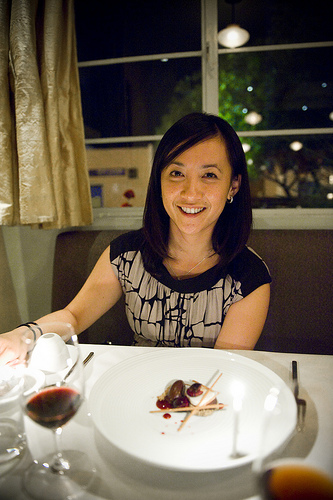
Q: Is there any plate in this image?
A: Yes, there is a plate.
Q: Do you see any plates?
A: Yes, there is a plate.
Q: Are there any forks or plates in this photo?
A: Yes, there is a plate.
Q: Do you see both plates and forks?
A: Yes, there are both a plate and a fork.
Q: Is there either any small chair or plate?
A: Yes, there is a small plate.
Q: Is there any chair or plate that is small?
A: Yes, the plate is small.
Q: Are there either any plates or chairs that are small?
A: Yes, the plate is small.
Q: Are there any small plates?
A: Yes, there is a small plate.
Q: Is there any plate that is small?
A: Yes, there is a plate that is small.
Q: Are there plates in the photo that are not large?
A: Yes, there is a small plate.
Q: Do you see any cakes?
A: No, there are no cakes.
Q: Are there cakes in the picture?
A: No, there are no cakes.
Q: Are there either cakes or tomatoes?
A: No, there are no cakes or tomatoes.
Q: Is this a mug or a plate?
A: This is a plate.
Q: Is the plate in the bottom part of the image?
A: Yes, the plate is in the bottom of the image.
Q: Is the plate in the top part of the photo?
A: No, the plate is in the bottom of the image.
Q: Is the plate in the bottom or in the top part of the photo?
A: The plate is in the bottom of the image.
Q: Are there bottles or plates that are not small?
A: No, there is a plate but it is small.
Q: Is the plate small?
A: Yes, the plate is small.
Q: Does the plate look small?
A: Yes, the plate is small.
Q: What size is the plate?
A: The plate is small.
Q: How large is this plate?
A: The plate is small.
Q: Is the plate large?
A: No, the plate is small.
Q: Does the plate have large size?
A: No, the plate is small.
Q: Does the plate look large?
A: No, the plate is small.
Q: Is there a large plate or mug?
A: No, there is a plate but it is small.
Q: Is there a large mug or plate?
A: No, there is a plate but it is small.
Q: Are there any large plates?
A: No, there is a plate but it is small.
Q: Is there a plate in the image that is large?
A: No, there is a plate but it is small.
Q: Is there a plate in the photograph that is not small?
A: No, there is a plate but it is small.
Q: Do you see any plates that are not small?
A: No, there is a plate but it is small.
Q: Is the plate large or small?
A: The plate is small.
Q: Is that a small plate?
A: Yes, that is a small plate.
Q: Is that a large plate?
A: No, that is a small plate.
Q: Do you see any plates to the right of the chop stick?
A: Yes, there is a plate to the right of the chop stick.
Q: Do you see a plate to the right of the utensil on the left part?
A: Yes, there is a plate to the right of the chop stick.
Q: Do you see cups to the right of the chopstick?
A: No, there is a plate to the right of the chopstick.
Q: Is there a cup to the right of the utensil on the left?
A: No, there is a plate to the right of the chopstick.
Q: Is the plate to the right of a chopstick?
A: Yes, the plate is to the right of a chopstick.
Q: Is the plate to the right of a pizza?
A: No, the plate is to the right of a chopstick.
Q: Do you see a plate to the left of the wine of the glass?
A: No, the plate is to the right of the wine.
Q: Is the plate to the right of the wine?
A: Yes, the plate is to the right of the wine.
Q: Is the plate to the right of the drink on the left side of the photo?
A: Yes, the plate is to the right of the wine.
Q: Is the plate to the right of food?
A: No, the plate is to the right of the wine.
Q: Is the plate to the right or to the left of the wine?
A: The plate is to the right of the wine.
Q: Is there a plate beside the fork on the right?
A: Yes, there is a plate beside the fork.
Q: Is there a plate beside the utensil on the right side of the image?
A: Yes, there is a plate beside the fork.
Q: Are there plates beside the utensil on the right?
A: Yes, there is a plate beside the fork.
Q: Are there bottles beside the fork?
A: No, there is a plate beside the fork.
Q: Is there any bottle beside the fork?
A: No, there is a plate beside the fork.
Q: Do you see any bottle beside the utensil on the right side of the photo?
A: No, there is a plate beside the fork.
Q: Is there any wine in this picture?
A: Yes, there is wine.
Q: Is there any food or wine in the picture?
A: Yes, there is wine.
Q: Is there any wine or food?
A: Yes, there is wine.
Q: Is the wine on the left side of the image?
A: Yes, the wine is on the left of the image.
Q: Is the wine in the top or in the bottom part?
A: The wine is in the bottom of the image.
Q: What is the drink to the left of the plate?
A: The drink is wine.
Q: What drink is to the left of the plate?
A: The drink is wine.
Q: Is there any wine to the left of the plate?
A: Yes, there is wine to the left of the plate.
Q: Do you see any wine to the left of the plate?
A: Yes, there is wine to the left of the plate.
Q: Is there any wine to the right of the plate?
A: No, the wine is to the left of the plate.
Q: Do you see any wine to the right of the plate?
A: No, the wine is to the left of the plate.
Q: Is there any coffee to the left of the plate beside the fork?
A: No, there is wine to the left of the plate.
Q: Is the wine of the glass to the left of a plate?
A: Yes, the wine is to the left of a plate.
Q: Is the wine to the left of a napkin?
A: No, the wine is to the left of a plate.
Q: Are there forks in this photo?
A: Yes, there is a fork.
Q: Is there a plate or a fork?
A: Yes, there is a fork.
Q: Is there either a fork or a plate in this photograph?
A: Yes, there is a fork.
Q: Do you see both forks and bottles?
A: No, there is a fork but no bottles.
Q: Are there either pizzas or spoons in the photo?
A: No, there are no spoons or pizzas.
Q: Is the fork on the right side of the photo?
A: Yes, the fork is on the right of the image.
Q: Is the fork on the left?
A: No, the fork is on the right of the image.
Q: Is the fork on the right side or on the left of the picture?
A: The fork is on the right of the image.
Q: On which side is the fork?
A: The fork is on the right of the image.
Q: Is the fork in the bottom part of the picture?
A: Yes, the fork is in the bottom of the image.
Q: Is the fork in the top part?
A: No, the fork is in the bottom of the image.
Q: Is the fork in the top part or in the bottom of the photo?
A: The fork is in the bottom of the image.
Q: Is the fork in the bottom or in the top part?
A: The fork is in the bottom of the image.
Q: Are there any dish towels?
A: No, there are no dish towels.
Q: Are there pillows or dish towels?
A: No, there are no dish towels or pillows.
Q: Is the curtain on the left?
A: Yes, the curtain is on the left of the image.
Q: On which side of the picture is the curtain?
A: The curtain is on the left of the image.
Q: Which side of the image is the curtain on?
A: The curtain is on the left of the image.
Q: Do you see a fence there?
A: No, there are no fences.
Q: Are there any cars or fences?
A: No, there are no fences or cars.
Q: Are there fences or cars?
A: No, there are no fences or cars.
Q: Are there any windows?
A: Yes, there is a window.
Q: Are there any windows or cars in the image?
A: Yes, there is a window.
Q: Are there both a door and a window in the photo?
A: No, there is a window but no doors.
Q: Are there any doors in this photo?
A: No, there are no doors.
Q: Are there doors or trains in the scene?
A: No, there are no doors or trains.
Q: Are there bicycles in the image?
A: No, there are no bicycles.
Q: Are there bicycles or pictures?
A: No, there are no bicycles or pictures.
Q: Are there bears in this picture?
A: No, there are no bears.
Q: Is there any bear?
A: No, there are no bears.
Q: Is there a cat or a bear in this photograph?
A: No, there are no bears or cats.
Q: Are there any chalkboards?
A: No, there are no chalkboards.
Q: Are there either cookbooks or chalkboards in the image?
A: No, there are no chalkboards or cookbooks.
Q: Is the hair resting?
A: Yes, the hair is resting.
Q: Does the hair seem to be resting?
A: Yes, the hair is resting.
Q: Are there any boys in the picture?
A: No, there are no boys.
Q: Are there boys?
A: No, there are no boys.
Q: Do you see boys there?
A: No, there are no boys.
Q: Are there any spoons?
A: No, there are no spoons.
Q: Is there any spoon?
A: No, there are no spoons.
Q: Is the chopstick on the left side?
A: Yes, the chopstick is on the left of the image.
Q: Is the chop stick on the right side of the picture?
A: No, the chop stick is on the left of the image.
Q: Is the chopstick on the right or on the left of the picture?
A: The chopstick is on the left of the image.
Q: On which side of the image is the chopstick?
A: The chopstick is on the left of the image.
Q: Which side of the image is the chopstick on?
A: The chopstick is on the left of the image.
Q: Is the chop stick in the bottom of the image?
A: Yes, the chop stick is in the bottom of the image.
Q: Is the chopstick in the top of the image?
A: No, the chopstick is in the bottom of the image.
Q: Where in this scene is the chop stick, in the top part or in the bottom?
A: The chop stick is in the bottom of the image.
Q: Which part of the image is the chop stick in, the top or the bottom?
A: The chop stick is in the bottom of the image.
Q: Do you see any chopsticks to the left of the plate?
A: Yes, there is a chopstick to the left of the plate.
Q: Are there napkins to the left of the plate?
A: No, there is a chopstick to the left of the plate.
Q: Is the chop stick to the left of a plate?
A: Yes, the chop stick is to the left of a plate.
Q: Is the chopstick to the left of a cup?
A: No, the chopstick is to the left of a plate.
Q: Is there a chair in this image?
A: No, there are no chairs.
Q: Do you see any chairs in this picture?
A: No, there are no chairs.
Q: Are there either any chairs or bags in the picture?
A: No, there are no chairs or bags.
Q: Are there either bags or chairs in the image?
A: No, there are no chairs or bags.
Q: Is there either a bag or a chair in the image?
A: No, there are no chairs or bags.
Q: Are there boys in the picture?
A: No, there are no boys.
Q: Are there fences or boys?
A: No, there are no boys or fences.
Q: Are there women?
A: Yes, there is a woman.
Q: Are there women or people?
A: Yes, there is a woman.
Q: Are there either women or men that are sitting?
A: Yes, the woman is sitting.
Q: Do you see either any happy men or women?
A: Yes, there is a happy woman.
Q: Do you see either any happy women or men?
A: Yes, there is a happy woman.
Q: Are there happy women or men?
A: Yes, there is a happy woman.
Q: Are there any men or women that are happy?
A: Yes, the woman is happy.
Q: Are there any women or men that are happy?
A: Yes, the woman is happy.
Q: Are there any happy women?
A: Yes, there is a happy woman.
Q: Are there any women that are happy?
A: Yes, there is a woman that is happy.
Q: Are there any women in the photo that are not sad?
A: Yes, there is a happy woman.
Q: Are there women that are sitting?
A: Yes, there is a woman that is sitting.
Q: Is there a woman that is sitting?
A: Yes, there is a woman that is sitting.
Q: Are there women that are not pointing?
A: Yes, there is a woman that is sitting.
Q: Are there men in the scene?
A: No, there are no men.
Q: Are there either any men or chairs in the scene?
A: No, there are no men or chairs.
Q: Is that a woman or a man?
A: That is a woman.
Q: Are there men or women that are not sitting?
A: No, there is a woman but she is sitting.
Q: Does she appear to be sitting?
A: Yes, the woman is sitting.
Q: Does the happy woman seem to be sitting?
A: Yes, the woman is sitting.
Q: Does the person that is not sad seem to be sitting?
A: Yes, the woman is sitting.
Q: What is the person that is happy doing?
A: The woman is sitting.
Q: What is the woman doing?
A: The woman is sitting.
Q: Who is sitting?
A: The woman is sitting.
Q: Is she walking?
A: No, the woman is sitting.